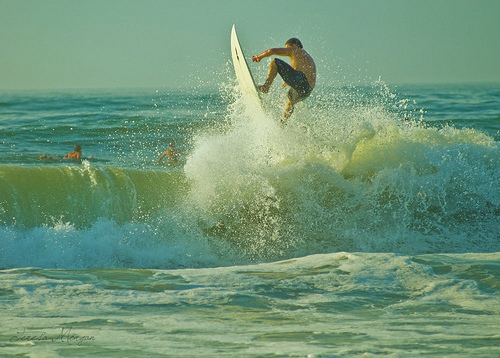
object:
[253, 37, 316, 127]
man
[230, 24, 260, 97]
board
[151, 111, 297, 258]
water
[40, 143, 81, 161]
person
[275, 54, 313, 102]
shorts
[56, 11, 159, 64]
sky